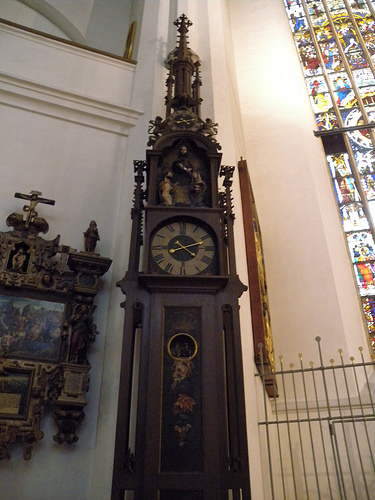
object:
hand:
[168, 237, 201, 262]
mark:
[199, 240, 215, 258]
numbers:
[190, 257, 207, 277]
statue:
[65, 205, 112, 256]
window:
[306, 40, 373, 150]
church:
[0, 0, 374, 497]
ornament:
[157, 145, 208, 205]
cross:
[167, 9, 198, 50]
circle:
[167, 329, 201, 363]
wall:
[8, 102, 113, 468]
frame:
[0, 185, 114, 465]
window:
[275, 14, 373, 167]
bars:
[300, 2, 322, 84]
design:
[154, 300, 209, 475]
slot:
[121, 292, 141, 465]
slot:
[218, 302, 241, 471]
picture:
[236, 156, 287, 404]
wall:
[206, 6, 291, 498]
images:
[131, 100, 225, 145]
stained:
[252, 238, 373, 407]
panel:
[283, 0, 375, 375]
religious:
[9, 166, 107, 428]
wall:
[15, 273, 120, 467]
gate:
[260, 398, 375, 500]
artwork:
[236, 152, 282, 399]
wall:
[253, 356, 291, 433]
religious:
[152, 172, 211, 236]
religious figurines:
[154, 142, 209, 211]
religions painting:
[0, 185, 113, 469]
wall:
[3, 7, 217, 499]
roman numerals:
[149, 219, 213, 280]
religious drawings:
[161, 305, 204, 471]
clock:
[110, 8, 250, 497]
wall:
[214, 1, 373, 497]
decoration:
[282, 169, 326, 333]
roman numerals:
[150, 221, 220, 276]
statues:
[158, 156, 207, 202]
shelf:
[150, 201, 225, 207]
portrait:
[3, 291, 59, 358]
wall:
[1, 100, 116, 490]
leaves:
[173, 394, 196, 411]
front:
[144, 289, 221, 478]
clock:
[146, 216, 218, 276]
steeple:
[160, 6, 211, 123]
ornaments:
[149, 108, 217, 140]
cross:
[0, 183, 63, 212]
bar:
[251, 332, 373, 497]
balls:
[310, 330, 327, 346]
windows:
[282, 1, 374, 358]